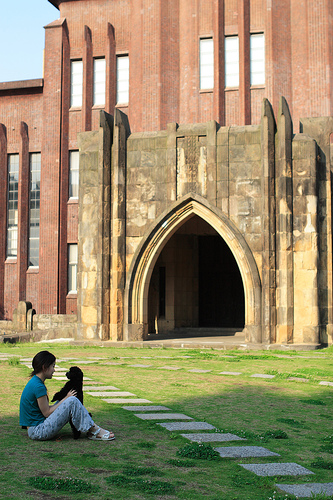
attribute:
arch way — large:
[121, 189, 265, 347]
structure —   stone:
[56, 103, 331, 489]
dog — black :
[51, 357, 112, 402]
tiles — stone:
[1, 350, 331, 498]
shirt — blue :
[18, 373, 52, 422]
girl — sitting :
[13, 344, 119, 453]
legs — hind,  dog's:
[66, 419, 78, 434]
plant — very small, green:
[169, 431, 225, 470]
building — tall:
[47, 12, 327, 248]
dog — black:
[51, 367, 84, 403]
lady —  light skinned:
[18, 348, 118, 444]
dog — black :
[51, 365, 83, 409]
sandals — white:
[85, 419, 117, 445]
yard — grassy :
[1, 343, 332, 498]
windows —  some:
[6, 153, 41, 273]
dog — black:
[49, 353, 91, 438]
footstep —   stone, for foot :
[142, 410, 275, 485]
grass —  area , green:
[0, 341, 331, 497]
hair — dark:
[27, 350, 57, 377]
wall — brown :
[1, 1, 330, 348]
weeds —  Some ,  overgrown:
[28, 471, 102, 497]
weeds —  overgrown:
[104, 471, 176, 496]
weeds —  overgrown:
[177, 441, 221, 461]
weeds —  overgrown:
[263, 425, 287, 442]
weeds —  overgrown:
[310, 454, 331, 470]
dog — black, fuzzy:
[51, 366, 93, 436]